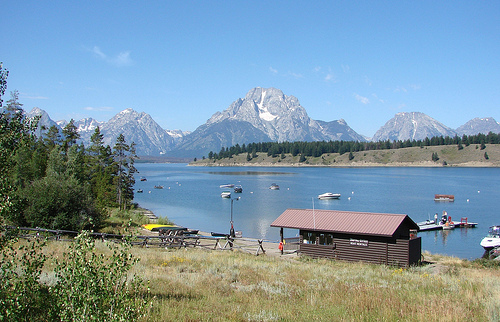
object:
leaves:
[0, 217, 158, 321]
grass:
[39, 241, 496, 321]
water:
[133, 160, 499, 255]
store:
[269, 209, 422, 270]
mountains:
[1, 86, 500, 152]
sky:
[4, 4, 498, 132]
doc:
[417, 221, 478, 231]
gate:
[17, 226, 280, 254]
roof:
[270, 208, 422, 237]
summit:
[235, 86, 302, 112]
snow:
[257, 89, 278, 121]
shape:
[374, 111, 454, 145]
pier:
[405, 218, 479, 234]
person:
[440, 211, 448, 224]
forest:
[212, 131, 500, 160]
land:
[196, 145, 499, 168]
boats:
[138, 172, 465, 216]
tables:
[151, 227, 200, 247]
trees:
[35, 118, 144, 206]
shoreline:
[126, 205, 290, 244]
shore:
[264, 241, 472, 273]